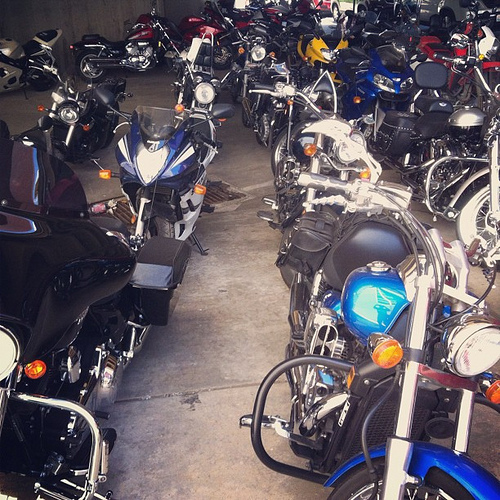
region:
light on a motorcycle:
[187, 76, 217, 109]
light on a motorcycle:
[367, 330, 409, 377]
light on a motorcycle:
[442, 314, 498, 382]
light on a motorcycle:
[334, 129, 367, 164]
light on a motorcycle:
[300, 138, 323, 161]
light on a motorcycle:
[21, 354, 48, 384]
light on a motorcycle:
[0, 318, 23, 388]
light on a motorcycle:
[95, 168, 112, 183]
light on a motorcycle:
[190, 180, 205, 200]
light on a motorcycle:
[134, 142, 175, 189]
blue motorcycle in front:
[293, 209, 495, 498]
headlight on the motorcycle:
[460, 323, 497, 379]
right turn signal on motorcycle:
[366, 331, 401, 366]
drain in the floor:
[205, 169, 246, 221]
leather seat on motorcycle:
[328, 204, 398, 292]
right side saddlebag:
[281, 203, 333, 292]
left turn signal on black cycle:
[25, 358, 45, 383]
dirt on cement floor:
[174, 381, 200, 415]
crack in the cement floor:
[131, 383, 261, 403]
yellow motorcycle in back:
[302, 10, 347, 74]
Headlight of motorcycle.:
[445, 319, 499, 380]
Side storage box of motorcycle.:
[131, 237, 191, 331]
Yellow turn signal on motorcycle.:
[372, 338, 406, 370]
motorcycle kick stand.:
[91, 155, 105, 172]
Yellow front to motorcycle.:
[299, 33, 351, 69]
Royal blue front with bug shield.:
[111, 104, 205, 195]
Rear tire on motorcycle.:
[76, 50, 108, 84]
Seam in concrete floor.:
[133, 373, 249, 417]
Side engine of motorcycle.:
[292, 308, 361, 412]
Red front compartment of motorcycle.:
[124, 29, 156, 44]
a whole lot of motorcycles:
[21, 33, 491, 495]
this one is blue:
[343, 263, 444, 495]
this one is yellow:
[301, 29, 358, 84]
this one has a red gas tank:
[72, 8, 177, 86]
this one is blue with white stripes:
[113, 108, 200, 233]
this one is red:
[412, 9, 486, 82]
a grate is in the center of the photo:
[90, 166, 257, 221]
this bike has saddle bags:
[371, 102, 478, 169]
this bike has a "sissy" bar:
[189, 31, 224, 80]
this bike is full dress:
[6, 130, 191, 497]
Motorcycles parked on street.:
[187, 45, 468, 407]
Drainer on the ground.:
[204, 171, 242, 223]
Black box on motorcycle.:
[134, 239, 201, 324]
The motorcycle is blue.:
[349, 264, 404, 351]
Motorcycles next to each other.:
[191, 25, 453, 165]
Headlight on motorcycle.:
[431, 295, 496, 367]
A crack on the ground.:
[132, 370, 307, 403]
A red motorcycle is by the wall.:
[58, 22, 186, 74]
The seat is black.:
[319, 223, 407, 273]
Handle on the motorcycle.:
[286, 146, 449, 258]